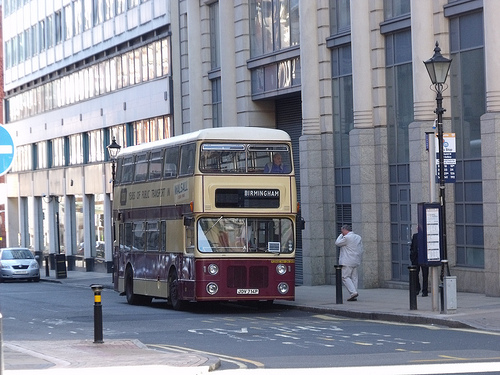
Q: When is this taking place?
A: Daytime.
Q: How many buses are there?
A: One.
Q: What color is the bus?
A: Yellow, white, maroon.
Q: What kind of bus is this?
A: Doubledecker bus.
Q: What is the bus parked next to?
A: Sidewalk.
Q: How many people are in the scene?
A: Two.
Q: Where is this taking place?
A: City street.